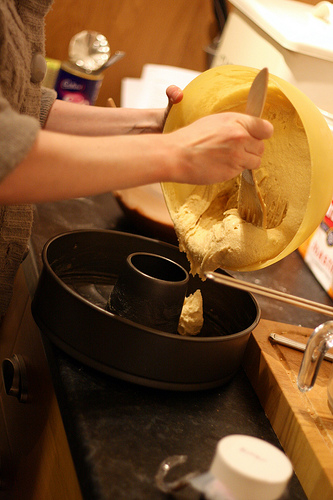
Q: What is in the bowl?
A: Cake mixture.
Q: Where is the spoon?
A: In the man's hand.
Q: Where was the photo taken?
A: A kitchen.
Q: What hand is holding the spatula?
A: Right hand.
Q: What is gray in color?
A: Sweater.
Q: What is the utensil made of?
A: Wood.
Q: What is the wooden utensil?
A: Fork.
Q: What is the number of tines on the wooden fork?
A: 5.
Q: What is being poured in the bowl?
A: Batter.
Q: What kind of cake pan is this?
A: Bundt.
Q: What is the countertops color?
A: Black.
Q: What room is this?
A: Kitchen.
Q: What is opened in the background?
A: Can.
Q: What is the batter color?
A: Yellow.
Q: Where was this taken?
A: In a kitchen.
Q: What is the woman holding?
A: A bowl and wooden utensil.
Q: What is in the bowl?
A: Batter.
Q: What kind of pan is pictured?
A: A bundt.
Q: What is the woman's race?
A: Caucasian.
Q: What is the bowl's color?
A: Yellow.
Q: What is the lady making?
A: A cake.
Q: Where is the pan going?
A: Into the oven.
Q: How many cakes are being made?
A: 1.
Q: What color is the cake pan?
A: Black.